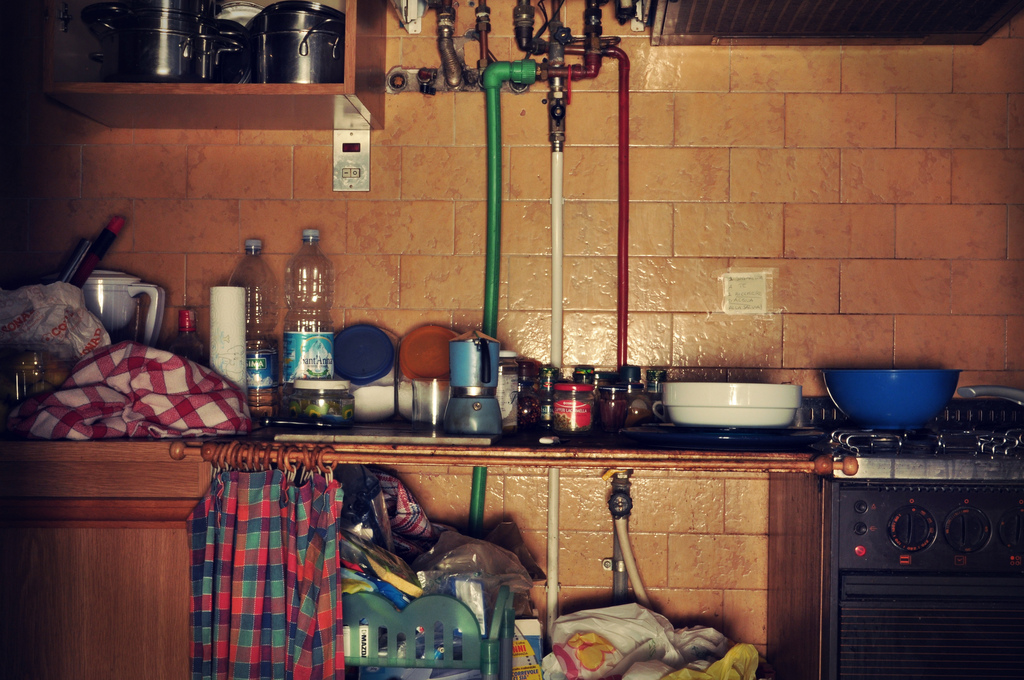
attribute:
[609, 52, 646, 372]
supply pipe — red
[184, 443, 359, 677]
curtain — red, green, blue, plaid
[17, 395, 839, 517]
countertop — cluttered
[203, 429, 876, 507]
counter — wooden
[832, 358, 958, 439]
serving bowl — blue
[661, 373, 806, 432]
bowl — white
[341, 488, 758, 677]
compartment — cluttered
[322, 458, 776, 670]
compartment — cluttered